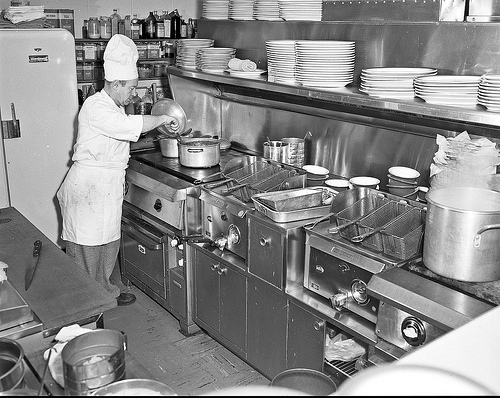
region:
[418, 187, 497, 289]
large silver stock pot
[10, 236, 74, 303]
silver and black cutting knife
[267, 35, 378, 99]
stack of dinner plates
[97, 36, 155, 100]
white folded chef hat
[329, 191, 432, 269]
three frying trays near fryer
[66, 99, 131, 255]
white shirt and apron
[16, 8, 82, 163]
white colored fridge wth round edge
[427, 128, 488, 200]
baskets with parchment paper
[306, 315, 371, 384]
open slide door under fryer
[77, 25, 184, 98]
shelves of seasonings and cooking items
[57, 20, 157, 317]
A chef standing in a kitchen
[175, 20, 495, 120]
Dishes stacked on the shelf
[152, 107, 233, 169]
A pot of soup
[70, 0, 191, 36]
Spices and ingredients for a recipe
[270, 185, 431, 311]
A deep frier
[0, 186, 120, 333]
A knife on a cutting board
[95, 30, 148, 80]
The chef's hat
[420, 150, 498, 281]
A big pot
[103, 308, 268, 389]
The floor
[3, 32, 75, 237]
A fridge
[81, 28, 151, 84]
A chef's hat on his head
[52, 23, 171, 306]
A chef in the kitchen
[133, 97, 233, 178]
A chef cooking in the kitchen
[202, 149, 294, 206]
A set of three deep fryer baskets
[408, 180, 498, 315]
A large stock pot sitting on counter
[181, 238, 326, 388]
Storage cabinets in the kitchen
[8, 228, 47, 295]
A knife sitting on the table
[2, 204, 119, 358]
A table sitting in the kitchen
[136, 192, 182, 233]
A temperature dial on the stove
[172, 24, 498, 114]
Serving plates in the kitchen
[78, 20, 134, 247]
this is a man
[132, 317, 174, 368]
this is the floor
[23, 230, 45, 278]
this is a knife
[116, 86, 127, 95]
the man is light skinned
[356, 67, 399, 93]
these are the plates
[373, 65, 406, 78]
the plate is white in color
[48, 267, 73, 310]
this is a table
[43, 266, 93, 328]
the table is wooden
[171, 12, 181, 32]
this is a bottle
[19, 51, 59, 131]
this is a refrigerator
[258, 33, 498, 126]
stacks of plates on shelf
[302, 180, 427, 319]
industrial kitchen fryer baskets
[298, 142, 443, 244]
stacks of soup bowls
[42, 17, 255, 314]
chef preparing food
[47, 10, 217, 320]
man in apron and chef hat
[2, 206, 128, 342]
chef knife laying on butcher block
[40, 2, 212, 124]
labeled spices on shelves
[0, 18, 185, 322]
chef standing next to refrigerator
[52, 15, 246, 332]
middle aged man in chefs hat and apron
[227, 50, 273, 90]
towl rolled up and on top of plate